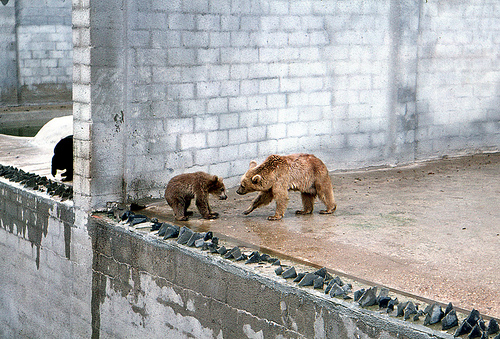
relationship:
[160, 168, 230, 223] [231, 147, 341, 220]
small bear in front of big bear